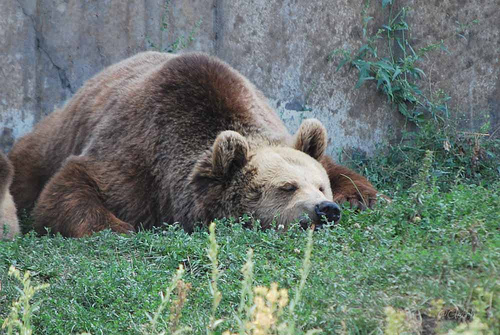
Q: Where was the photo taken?
A: At a zoo.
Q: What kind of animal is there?
A: A bear.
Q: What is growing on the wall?
A: A vine.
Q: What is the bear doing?
A: Sleeping.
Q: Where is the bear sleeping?
A: On the ground.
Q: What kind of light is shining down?
A: Sunlight.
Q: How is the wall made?
A: Cement.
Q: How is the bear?
A: Sleeping.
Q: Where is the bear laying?
A: Grass.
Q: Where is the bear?
A: In front of wall.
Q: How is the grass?
A: Short.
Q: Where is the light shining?
A: On bear.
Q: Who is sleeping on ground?
A: A bear.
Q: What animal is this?
A: Bear.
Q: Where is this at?
A: A zoo.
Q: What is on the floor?
A: Grass.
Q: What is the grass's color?
A: Green.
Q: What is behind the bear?
A: A stone wall.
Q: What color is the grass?
A: Green.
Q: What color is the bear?
A: Brown.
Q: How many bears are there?
A: One.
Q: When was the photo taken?
A: Daytime.